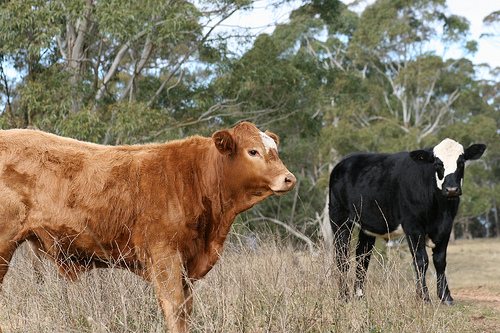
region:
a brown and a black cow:
[3, 56, 463, 297]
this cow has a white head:
[305, 112, 487, 319]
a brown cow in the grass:
[8, 103, 303, 330]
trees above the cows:
[17, 8, 495, 111]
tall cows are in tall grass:
[235, 263, 413, 329]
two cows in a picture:
[24, 94, 492, 319]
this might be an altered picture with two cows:
[19, 82, 484, 330]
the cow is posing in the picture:
[6, 115, 281, 330]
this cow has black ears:
[400, 129, 487, 202]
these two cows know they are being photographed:
[7, 107, 482, 323]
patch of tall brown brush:
[9, 259, 72, 331]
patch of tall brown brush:
[82, 274, 142, 331]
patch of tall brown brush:
[209, 242, 272, 331]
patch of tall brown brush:
[300, 259, 372, 331]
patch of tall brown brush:
[375, 251, 428, 331]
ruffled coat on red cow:
[4, 131, 55, 227]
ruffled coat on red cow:
[67, 146, 131, 258]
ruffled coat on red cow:
[138, 152, 201, 266]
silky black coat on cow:
[342, 167, 434, 225]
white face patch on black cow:
[430, 131, 471, 196]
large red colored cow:
[139, 121, 316, 219]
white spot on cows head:
[242, 125, 282, 166]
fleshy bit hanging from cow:
[22, 222, 119, 292]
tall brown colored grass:
[46, 274, 299, 326]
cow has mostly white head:
[421, 130, 487, 204]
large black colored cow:
[308, 143, 475, 297]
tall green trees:
[125, 50, 461, 150]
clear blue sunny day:
[2, 46, 38, 110]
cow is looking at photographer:
[237, 136, 280, 171]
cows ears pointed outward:
[406, 144, 495, 168]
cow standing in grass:
[322, 128, 493, 299]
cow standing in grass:
[15, 115, 306, 321]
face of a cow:
[406, 141, 491, 199]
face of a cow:
[212, 111, 302, 208]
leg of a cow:
[406, 222, 433, 308]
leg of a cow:
[435, 221, 453, 302]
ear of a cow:
[400, 140, 431, 168]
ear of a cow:
[471, 136, 486, 172]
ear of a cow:
[203, 126, 244, 158]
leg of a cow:
[144, 233, 194, 331]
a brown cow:
[1, 119, 311, 331]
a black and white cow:
[316, 138, 496, 302]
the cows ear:
[212, 127, 237, 158]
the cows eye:
[239, 145, 266, 159]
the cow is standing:
[5, 120, 294, 331]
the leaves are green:
[248, 57, 300, 90]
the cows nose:
[443, 183, 462, 196]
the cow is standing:
[325, 136, 485, 308]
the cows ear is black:
[410, 143, 440, 165]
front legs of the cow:
[403, 248, 458, 307]